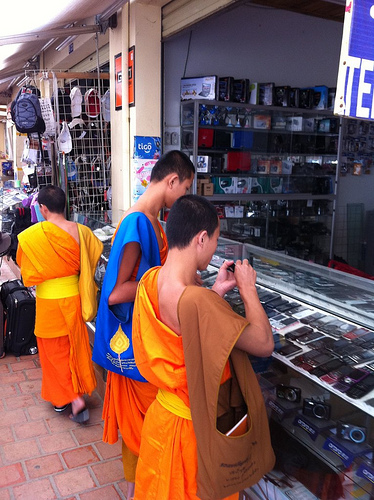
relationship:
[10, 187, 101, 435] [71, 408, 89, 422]
man wearing sandal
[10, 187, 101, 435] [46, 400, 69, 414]
man wearing sandal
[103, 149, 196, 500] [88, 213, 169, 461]
man wearing robe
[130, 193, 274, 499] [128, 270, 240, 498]
man wearing robe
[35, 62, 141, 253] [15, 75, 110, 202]
rack filled with merchandise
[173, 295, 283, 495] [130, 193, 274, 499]
bag over shoulder of man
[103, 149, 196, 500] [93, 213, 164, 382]
man wearing bag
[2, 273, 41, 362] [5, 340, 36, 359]
suitcase with wheels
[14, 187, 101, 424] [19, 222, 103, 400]
man wearing clothes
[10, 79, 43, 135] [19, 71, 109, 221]
backpack hanging on rack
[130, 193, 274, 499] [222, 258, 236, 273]
man looking at camera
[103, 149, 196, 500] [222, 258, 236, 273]
man looking at camera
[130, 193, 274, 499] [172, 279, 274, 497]
man has a bag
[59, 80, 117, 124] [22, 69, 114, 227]
caps hanging on mesh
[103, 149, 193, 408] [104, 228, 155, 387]
man carrying bag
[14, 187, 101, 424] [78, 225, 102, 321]
man carrying bag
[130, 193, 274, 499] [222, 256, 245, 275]
man holding camera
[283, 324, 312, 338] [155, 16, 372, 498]
mobile in shop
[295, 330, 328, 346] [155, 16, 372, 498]
mobile in shop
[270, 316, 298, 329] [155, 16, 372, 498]
mobile in shop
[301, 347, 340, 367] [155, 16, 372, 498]
mobile in shop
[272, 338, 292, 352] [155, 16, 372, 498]
mobile in shop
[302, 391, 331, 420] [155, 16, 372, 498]
camera in shop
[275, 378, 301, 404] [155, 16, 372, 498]
camera in shop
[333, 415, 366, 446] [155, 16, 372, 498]
camera in shop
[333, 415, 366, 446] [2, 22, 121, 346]
camera in shop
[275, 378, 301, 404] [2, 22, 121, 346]
camera in shop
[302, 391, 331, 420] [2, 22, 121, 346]
camera in shop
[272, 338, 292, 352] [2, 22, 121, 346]
mobile in shop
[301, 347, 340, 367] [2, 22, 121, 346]
mobile in shop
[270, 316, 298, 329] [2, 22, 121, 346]
mobile in shop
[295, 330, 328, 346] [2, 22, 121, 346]
mobile in shop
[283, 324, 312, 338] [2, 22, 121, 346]
mobile in shop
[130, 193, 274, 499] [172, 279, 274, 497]
man holding bag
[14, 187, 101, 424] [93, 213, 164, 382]
man holding bag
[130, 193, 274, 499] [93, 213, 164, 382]
man holding bag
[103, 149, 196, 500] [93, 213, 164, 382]
man holding bag